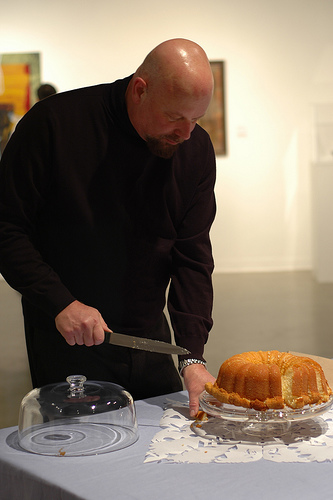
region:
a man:
[2, 37, 234, 423]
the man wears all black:
[3, 32, 228, 452]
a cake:
[198, 339, 332, 430]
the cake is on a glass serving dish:
[193, 343, 331, 443]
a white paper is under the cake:
[145, 379, 331, 469]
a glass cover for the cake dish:
[9, 371, 151, 459]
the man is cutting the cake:
[1, 33, 327, 491]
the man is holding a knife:
[6, 33, 223, 423]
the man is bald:
[4, 33, 225, 425]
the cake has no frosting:
[201, 340, 332, 418]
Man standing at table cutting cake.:
[2, 34, 217, 417]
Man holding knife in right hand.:
[54, 308, 191, 358]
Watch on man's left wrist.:
[177, 356, 207, 377]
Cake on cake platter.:
[202, 346, 329, 411]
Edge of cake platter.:
[199, 406, 328, 440]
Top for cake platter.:
[13, 374, 142, 456]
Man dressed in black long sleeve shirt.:
[2, 71, 229, 362]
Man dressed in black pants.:
[20, 310, 196, 417]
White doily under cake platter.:
[141, 395, 332, 468]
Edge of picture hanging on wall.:
[200, 55, 232, 160]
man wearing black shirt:
[67, 53, 228, 268]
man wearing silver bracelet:
[162, 336, 210, 382]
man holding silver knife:
[73, 326, 205, 368]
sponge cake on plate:
[219, 340, 327, 433]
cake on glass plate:
[204, 350, 320, 457]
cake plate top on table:
[29, 372, 140, 473]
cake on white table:
[218, 348, 309, 493]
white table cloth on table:
[144, 398, 304, 493]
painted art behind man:
[2, 52, 60, 121]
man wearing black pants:
[43, 293, 195, 406]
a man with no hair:
[139, 41, 236, 119]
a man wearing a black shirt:
[93, 78, 194, 218]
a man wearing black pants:
[26, 113, 185, 372]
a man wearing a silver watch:
[166, 353, 214, 381]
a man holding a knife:
[31, 308, 200, 358]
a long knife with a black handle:
[66, 321, 195, 360]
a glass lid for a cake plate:
[0, 367, 150, 450]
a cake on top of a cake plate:
[200, 344, 325, 434]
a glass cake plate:
[237, 360, 323, 444]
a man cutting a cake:
[118, 342, 253, 420]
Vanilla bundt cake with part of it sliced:
[199, 345, 332, 415]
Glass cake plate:
[193, 385, 330, 437]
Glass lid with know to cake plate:
[11, 371, 144, 460]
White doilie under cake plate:
[129, 373, 331, 469]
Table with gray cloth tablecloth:
[2, 351, 327, 497]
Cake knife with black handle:
[98, 321, 196, 360]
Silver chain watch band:
[173, 354, 211, 376]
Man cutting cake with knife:
[2, 30, 238, 494]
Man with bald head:
[120, 33, 226, 157]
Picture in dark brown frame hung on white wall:
[196, 56, 235, 168]